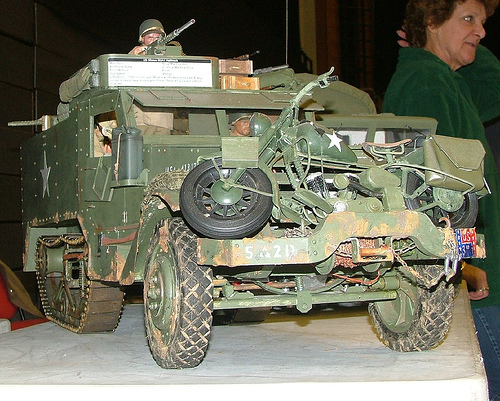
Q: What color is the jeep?
A: Green.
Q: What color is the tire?
A: Black.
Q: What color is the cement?
A: Light grey.